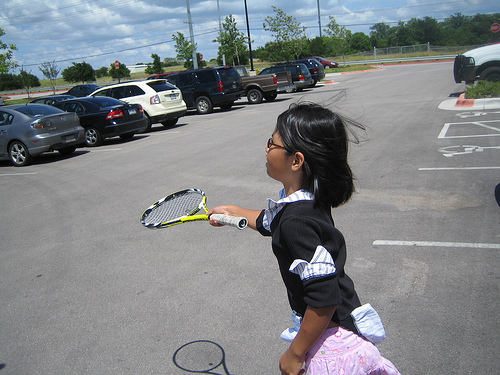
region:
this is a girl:
[225, 105, 346, 372]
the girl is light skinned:
[295, 327, 338, 350]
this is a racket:
[133, 192, 198, 223]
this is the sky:
[21, 8, 152, 58]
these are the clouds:
[49, 13, 89, 30]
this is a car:
[16, 111, 63, 166]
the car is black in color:
[91, 109, 105, 126]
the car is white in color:
[145, 95, 174, 120]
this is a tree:
[213, 16, 253, 68]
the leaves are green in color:
[222, 22, 240, 38]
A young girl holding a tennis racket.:
[136, 72, 398, 363]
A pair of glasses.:
[265, 136, 286, 147]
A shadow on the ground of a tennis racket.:
[170, 330, 236, 371]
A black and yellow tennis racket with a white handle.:
[140, 191, 247, 241]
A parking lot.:
[5, 42, 497, 370]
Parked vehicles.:
[2, 36, 497, 164]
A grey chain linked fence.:
[297, 42, 498, 59]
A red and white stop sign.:
[483, 22, 498, 35]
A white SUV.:
[89, 74, 189, 134]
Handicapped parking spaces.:
[439, 105, 498, 172]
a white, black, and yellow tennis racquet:
[139, 185, 246, 226]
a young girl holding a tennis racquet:
[140, 103, 400, 373]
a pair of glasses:
[264, 133, 297, 155]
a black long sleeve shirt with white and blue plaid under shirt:
[255, 185, 361, 323]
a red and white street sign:
[111, 58, 123, 80]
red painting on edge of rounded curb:
[450, 92, 475, 107]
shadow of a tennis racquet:
[172, 341, 231, 373]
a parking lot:
[1, 64, 499, 372]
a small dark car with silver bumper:
[258, 63, 315, 94]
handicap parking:
[422, 108, 499, 167]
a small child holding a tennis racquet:
[142, 99, 396, 374]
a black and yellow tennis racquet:
[143, 188, 246, 231]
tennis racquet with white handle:
[139, 188, 247, 233]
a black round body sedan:
[54, 97, 149, 144]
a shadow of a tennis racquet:
[173, 340, 228, 373]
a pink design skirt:
[299, 324, 402, 373]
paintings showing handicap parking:
[436, 106, 499, 163]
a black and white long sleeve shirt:
[259, 186, 364, 325]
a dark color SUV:
[165, 66, 242, 114]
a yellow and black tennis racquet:
[140, 188, 246, 228]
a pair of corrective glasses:
[266, 136, 296, 153]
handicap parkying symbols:
[437, 107, 499, 160]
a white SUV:
[87, 80, 186, 127]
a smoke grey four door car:
[2, 104, 82, 162]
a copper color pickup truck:
[222, 65, 292, 103]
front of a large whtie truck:
[454, 39, 499, 84]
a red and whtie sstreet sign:
[112, 60, 122, 82]